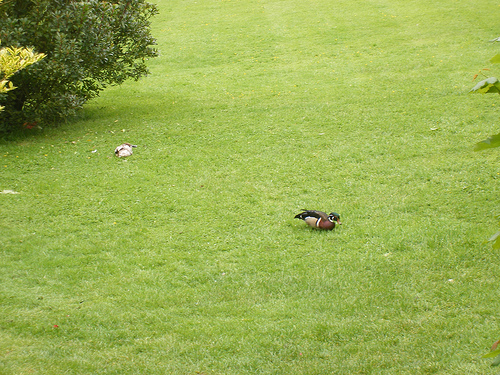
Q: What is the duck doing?
A: Walking.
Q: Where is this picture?
A: A park.